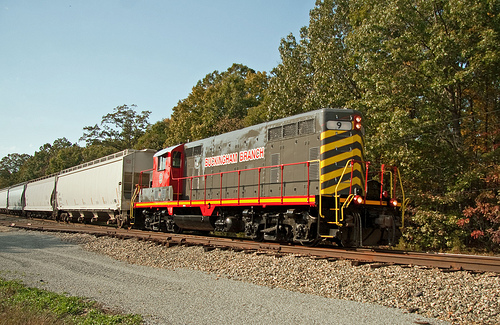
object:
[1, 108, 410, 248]
train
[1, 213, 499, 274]
track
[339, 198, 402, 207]
line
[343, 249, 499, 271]
rail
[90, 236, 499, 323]
gravel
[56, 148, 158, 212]
car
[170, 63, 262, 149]
tree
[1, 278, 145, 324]
grass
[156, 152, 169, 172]
window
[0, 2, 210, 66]
sky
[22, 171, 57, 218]
traincar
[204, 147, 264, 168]
labeling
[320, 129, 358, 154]
stripe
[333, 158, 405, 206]
railings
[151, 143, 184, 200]
portion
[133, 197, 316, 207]
stripe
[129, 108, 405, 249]
locomotive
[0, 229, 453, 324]
road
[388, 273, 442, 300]
gravel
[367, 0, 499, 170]
tree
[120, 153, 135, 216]
ladder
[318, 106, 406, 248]
front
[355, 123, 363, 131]
light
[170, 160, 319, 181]
rail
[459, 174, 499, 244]
leaves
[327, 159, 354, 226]
railing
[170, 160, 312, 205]
railing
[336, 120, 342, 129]
9